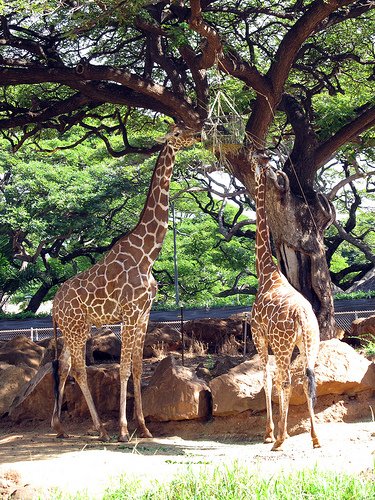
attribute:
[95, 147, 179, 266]
neck — long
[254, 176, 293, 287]
neck — long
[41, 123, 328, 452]
giraffes — standing, feeding, brown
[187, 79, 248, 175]
food — hanging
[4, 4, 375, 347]
tree — large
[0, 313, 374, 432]
rocks — large, brown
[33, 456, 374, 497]
grass — green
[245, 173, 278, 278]
neck — long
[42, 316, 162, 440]
legs — long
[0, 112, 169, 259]
leaves — green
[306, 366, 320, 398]
tail — black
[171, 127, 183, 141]
eyes — black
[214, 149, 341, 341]
trunk — large